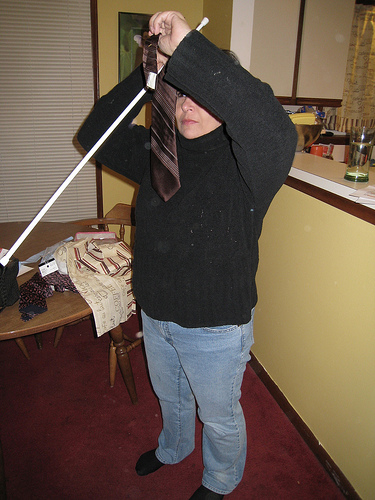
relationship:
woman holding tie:
[64, 11, 284, 497] [140, 32, 181, 199]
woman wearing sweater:
[74, 11, 302, 498] [55, 30, 302, 331]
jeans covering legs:
[137, 305, 251, 491] [171, 315, 254, 496]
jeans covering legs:
[137, 305, 251, 491] [137, 309, 196, 462]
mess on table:
[28, 227, 136, 328] [0, 215, 131, 344]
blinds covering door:
[0, 0, 98, 228] [2, 0, 105, 227]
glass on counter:
[345, 124, 371, 182] [254, 135, 374, 498]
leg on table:
[109, 322, 138, 403] [0, 220, 140, 404]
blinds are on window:
[0, 0, 98, 228] [0, 1, 110, 215]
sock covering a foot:
[134, 447, 164, 474] [133, 439, 196, 477]